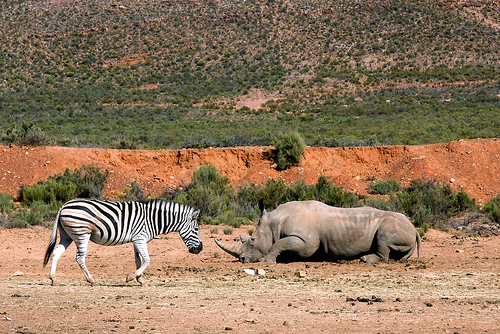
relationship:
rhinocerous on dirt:
[213, 198, 423, 265] [256, 264, 416, 324]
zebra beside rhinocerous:
[44, 195, 210, 285] [213, 198, 423, 265]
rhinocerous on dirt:
[213, 198, 428, 264] [241, 266, 390, 316]